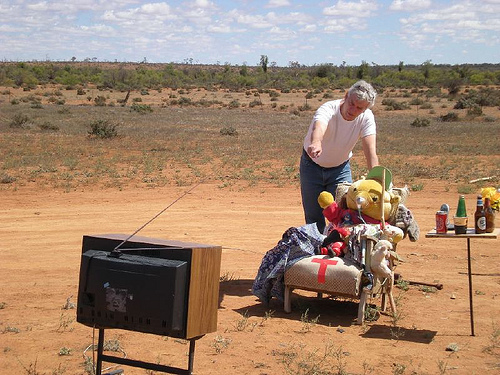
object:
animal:
[369, 237, 401, 320]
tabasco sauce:
[474, 195, 487, 233]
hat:
[364, 165, 393, 190]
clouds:
[0, 0, 500, 64]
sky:
[20, 4, 445, 64]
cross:
[311, 254, 338, 284]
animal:
[317, 169, 405, 259]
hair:
[345, 80, 377, 109]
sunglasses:
[329, 183, 394, 230]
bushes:
[438, 110, 463, 125]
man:
[296, 77, 382, 226]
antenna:
[113, 160, 226, 248]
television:
[74, 232, 224, 341]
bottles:
[453, 193, 469, 235]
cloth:
[248, 223, 318, 310]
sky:
[1, 0, 500, 64]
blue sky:
[0, 0, 500, 64]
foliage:
[111, 61, 141, 106]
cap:
[364, 165, 393, 191]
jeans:
[299, 148, 352, 228]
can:
[434, 210, 449, 233]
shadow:
[360, 322, 437, 345]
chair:
[281, 171, 411, 327]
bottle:
[474, 195, 489, 234]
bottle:
[484, 197, 496, 233]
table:
[425, 226, 500, 239]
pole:
[465, 237, 476, 336]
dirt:
[0, 175, 500, 375]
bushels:
[93, 94, 107, 106]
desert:
[0, 58, 500, 375]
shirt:
[300, 100, 377, 169]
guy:
[293, 75, 393, 246]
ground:
[0, 61, 500, 371]